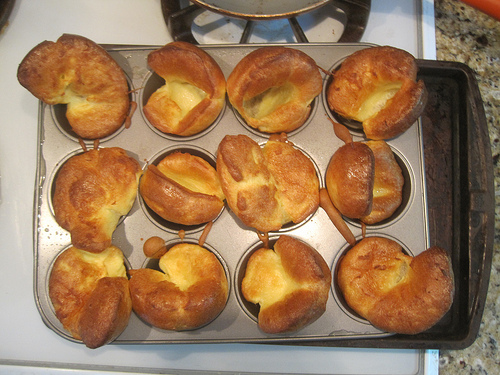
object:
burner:
[153, 0, 371, 48]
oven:
[0, 0, 443, 373]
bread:
[216, 131, 318, 237]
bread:
[143, 40, 225, 136]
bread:
[124, 235, 228, 328]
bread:
[133, 147, 227, 229]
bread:
[50, 145, 141, 253]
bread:
[326, 48, 427, 142]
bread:
[241, 234, 331, 338]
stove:
[158, 2, 372, 46]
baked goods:
[17, 33, 455, 347]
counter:
[434, 0, 500, 375]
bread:
[322, 141, 404, 225]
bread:
[335, 234, 455, 336]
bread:
[47, 244, 132, 350]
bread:
[220, 45, 321, 135]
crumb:
[144, 235, 166, 259]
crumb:
[315, 185, 359, 249]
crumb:
[332, 118, 352, 143]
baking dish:
[35, 42, 493, 348]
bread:
[17, 34, 128, 139]